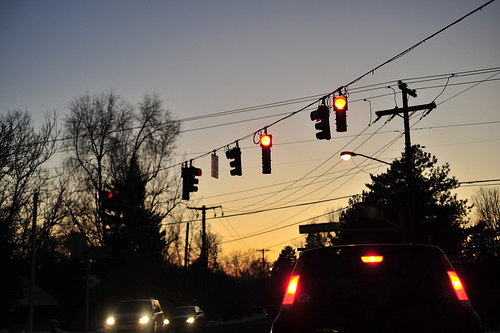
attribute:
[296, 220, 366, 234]
street sign — silhoutte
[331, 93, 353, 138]
light — light up, red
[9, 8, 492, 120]
sky — darkening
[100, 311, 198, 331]
headlights — bright white, turned on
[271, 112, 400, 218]
lines — power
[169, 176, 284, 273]
pole — tall 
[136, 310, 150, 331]
headlight — bright and fuzzy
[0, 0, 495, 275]
sky — orange, grey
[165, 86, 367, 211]
traffic lights — hanging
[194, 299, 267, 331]
snow — white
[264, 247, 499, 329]
lights — tail, illuminated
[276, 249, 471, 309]
break lights — car's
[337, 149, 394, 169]
street light — illuminated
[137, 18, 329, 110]
sky — urban, wire-filled, dusky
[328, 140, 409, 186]
light — lit, street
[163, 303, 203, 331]
car — one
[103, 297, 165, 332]
car — one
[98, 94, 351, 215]
lights — multiple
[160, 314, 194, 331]
head lights — illuminated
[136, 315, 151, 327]
head light — bright, lit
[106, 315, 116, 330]
head light — bright, lit